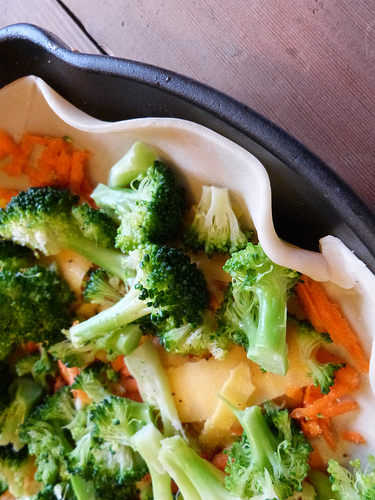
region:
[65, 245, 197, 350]
a green broccoli spear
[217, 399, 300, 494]
a green broccoli spear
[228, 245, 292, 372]
a green broccoli spear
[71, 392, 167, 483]
a green broccoli spear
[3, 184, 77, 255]
a green broccoli spear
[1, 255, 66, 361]
a green broccoli spear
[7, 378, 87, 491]
a green broccoli spear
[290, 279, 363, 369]
a small carrot slice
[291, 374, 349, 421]
a small carrot slice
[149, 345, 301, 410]
a slice of cheese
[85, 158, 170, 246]
green broccoli florets in salad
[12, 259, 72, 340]
green broccoli florets in salad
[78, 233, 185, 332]
green broccoli florets in salad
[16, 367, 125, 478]
green broccoli florets in salad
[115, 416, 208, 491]
green broccoli florets in salad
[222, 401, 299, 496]
green broccoli florets in salad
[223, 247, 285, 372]
green broccoli florets in salad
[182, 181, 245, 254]
green broccoli florets in salad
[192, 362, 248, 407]
orange cheese in salad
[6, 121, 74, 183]
orange slices of carrot in salad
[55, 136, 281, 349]
Broccoli on the plate.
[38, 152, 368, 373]
Vegetables on the plate.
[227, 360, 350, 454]
Orange carrots on the plate.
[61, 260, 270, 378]
Green broccoli on the plate.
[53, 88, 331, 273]
White plate with food.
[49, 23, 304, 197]
Black metal pan with white plate.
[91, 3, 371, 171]
Wood table under the plate.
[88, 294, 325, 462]
Cheese on the vegetables.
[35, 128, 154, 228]
Shredded carrots on the plate.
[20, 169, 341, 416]
Vegetables, cheese, and broccoli.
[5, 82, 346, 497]
white dish with vegetables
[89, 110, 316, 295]
green broccoli in white dish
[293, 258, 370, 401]
carrot slices in white dish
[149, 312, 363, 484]
cheese and broccoli mixed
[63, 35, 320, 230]
black dish outside white dish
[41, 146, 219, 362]
cut-up gree broccoli in dish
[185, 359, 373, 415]
white cheese in dish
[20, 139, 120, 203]
orange carrot pieces in dish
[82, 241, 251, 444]
green, orange, and yellow/white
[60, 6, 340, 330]
dish sitting on table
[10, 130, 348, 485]
bright green broccoli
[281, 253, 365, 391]
orange shreds of carrot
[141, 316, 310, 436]
thin slices of yellow cheese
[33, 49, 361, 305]
white uncooked dough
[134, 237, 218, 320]
dark green broccoli flowerettes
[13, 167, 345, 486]
colorful food in an uncooked crust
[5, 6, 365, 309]
food in a black skillet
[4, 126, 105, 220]
small pile of shredded carrots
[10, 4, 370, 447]
skillet of food on a wooden table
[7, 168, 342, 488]
mixture of varied food